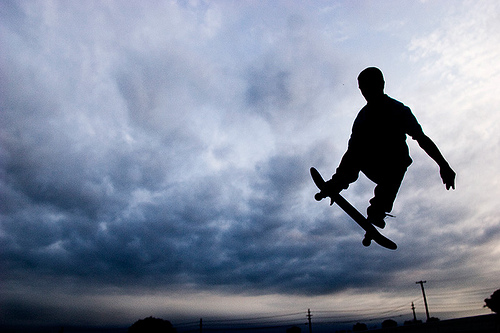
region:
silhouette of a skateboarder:
[296, 47, 469, 255]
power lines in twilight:
[123, 269, 494, 331]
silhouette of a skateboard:
[292, 158, 411, 260]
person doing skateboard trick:
[285, 47, 471, 264]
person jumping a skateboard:
[3, 3, 495, 330]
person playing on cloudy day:
[4, 4, 496, 329]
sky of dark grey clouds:
[3, 5, 498, 306]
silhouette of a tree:
[119, 298, 180, 331]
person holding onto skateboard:
[298, 55, 472, 265]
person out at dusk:
[3, 3, 493, 330]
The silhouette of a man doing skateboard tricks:
[302, 64, 459, 253]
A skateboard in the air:
[300, 163, 399, 254]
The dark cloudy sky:
[26, 162, 296, 286]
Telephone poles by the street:
[288, 276, 458, 330]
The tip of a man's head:
[123, 310, 174, 331]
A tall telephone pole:
[417, 277, 434, 320]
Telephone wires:
[315, 296, 424, 326]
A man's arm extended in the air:
[407, 114, 457, 198]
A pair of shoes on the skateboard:
[326, 171, 387, 229]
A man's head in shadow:
[353, 65, 392, 97]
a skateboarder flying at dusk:
[5, 5, 493, 330]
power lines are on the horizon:
[185, 276, 498, 331]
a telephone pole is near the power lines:
[415, 274, 437, 324]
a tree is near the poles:
[479, 279, 499, 324]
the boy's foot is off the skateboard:
[363, 207, 398, 250]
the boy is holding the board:
[296, 97, 373, 219]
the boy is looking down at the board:
[311, 62, 405, 245]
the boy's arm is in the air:
[350, 71, 459, 202]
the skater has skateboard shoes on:
[324, 173, 391, 236]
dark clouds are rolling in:
[8, 57, 493, 299]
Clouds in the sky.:
[33, 18, 201, 262]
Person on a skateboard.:
[291, 63, 465, 251]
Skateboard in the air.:
[296, 158, 413, 259]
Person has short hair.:
[352, 59, 399, 101]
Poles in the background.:
[409, 277, 441, 324]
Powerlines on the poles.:
[261, 291, 426, 331]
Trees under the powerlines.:
[346, 313, 445, 331]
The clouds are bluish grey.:
[80, 108, 257, 254]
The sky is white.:
[86, 287, 404, 322]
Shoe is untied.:
[364, 200, 405, 240]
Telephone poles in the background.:
[401, 265, 458, 330]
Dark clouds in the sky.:
[127, 167, 322, 301]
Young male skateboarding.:
[316, 53, 443, 267]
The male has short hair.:
[337, 51, 399, 235]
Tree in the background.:
[472, 278, 499, 323]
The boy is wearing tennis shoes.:
[332, 74, 407, 275]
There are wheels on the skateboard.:
[306, 162, 411, 277]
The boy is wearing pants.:
[328, 58, 421, 256]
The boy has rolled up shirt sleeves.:
[335, 67, 425, 217]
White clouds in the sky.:
[442, 33, 496, 85]